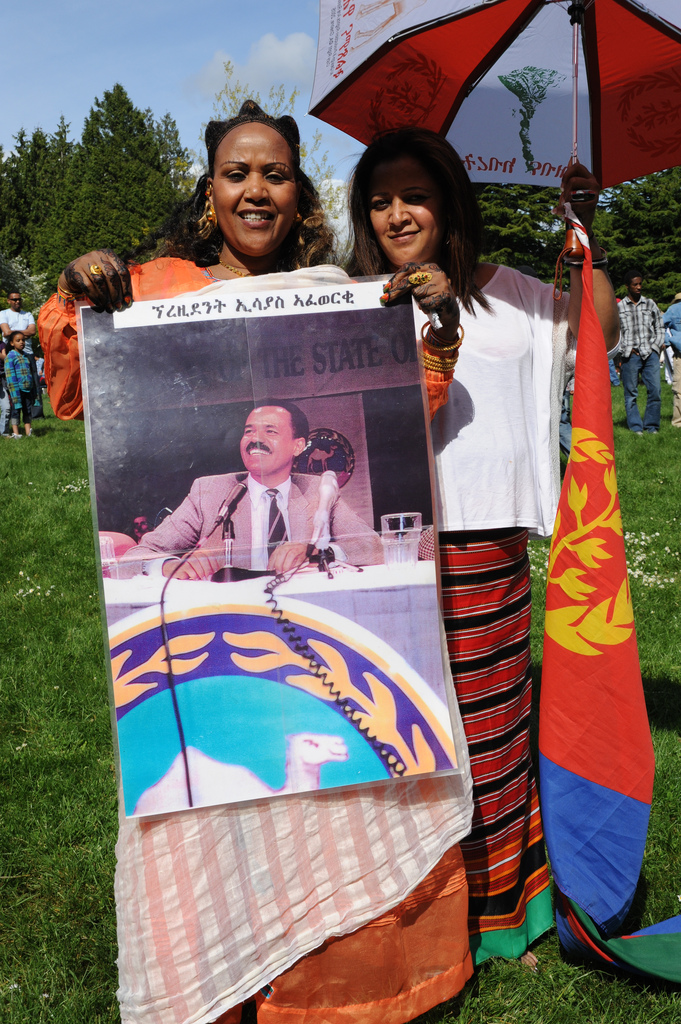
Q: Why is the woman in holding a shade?
A: It is sunny.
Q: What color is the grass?
A: Green.